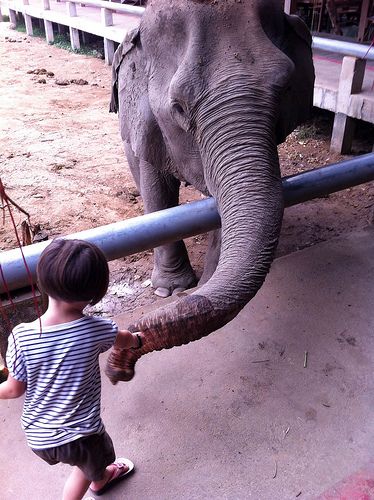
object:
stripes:
[7, 316, 120, 450]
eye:
[170, 96, 188, 120]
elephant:
[106, 1, 316, 386]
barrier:
[2, 152, 374, 295]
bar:
[1, 149, 373, 297]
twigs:
[254, 412, 307, 485]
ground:
[94, 368, 362, 495]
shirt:
[5, 314, 117, 450]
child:
[0, 236, 148, 499]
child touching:
[102, 294, 193, 384]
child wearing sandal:
[88, 453, 139, 499]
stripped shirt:
[1, 316, 119, 444]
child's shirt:
[7, 313, 119, 482]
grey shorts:
[33, 431, 114, 482]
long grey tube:
[311, 24, 374, 61]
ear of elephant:
[272, 8, 317, 144]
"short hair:
[35, 237, 110, 305]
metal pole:
[0, 158, 374, 308]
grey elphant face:
[148, 1, 308, 139]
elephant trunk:
[104, 89, 284, 388]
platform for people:
[263, 16, 369, 132]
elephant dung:
[27, 62, 87, 101]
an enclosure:
[75, 1, 347, 355]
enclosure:
[0, 0, 374, 288]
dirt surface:
[52, 121, 328, 327]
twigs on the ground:
[0, 182, 83, 322]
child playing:
[0, 235, 155, 498]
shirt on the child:
[5, 313, 119, 451]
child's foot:
[85, 461, 132, 498]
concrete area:
[98, 228, 372, 498]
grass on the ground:
[8, 12, 97, 63]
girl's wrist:
[129, 330, 138, 348]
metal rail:
[75, 201, 205, 263]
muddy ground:
[96, 141, 298, 287]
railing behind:
[309, 4, 371, 47]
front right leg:
[141, 147, 189, 273]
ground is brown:
[2, 32, 296, 310]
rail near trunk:
[104, 3, 147, 24]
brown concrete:
[181, 358, 345, 455]